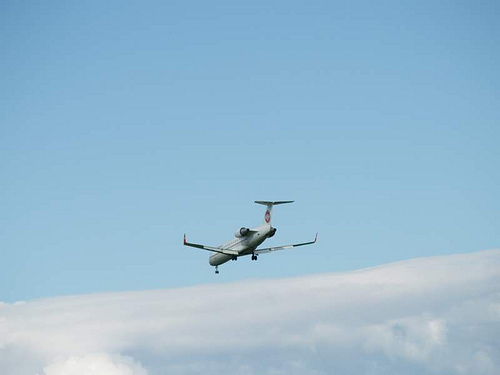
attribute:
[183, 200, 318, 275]
plane — flying, up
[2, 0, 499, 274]
air — blue, clear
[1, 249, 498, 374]
cloud — white, puffy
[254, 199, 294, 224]
tail — grey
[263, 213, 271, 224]
circle — red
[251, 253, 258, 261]
wheel — black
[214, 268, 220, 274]
wheel — black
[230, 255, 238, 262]
wheel — black